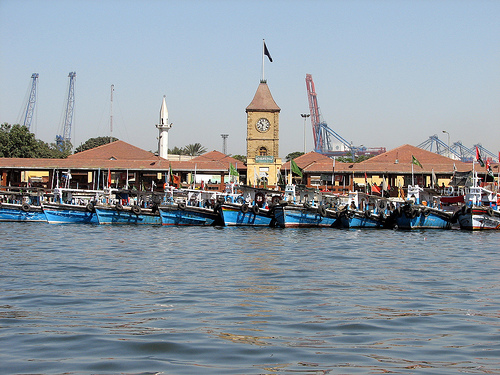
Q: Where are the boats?
A: Docked along the water.